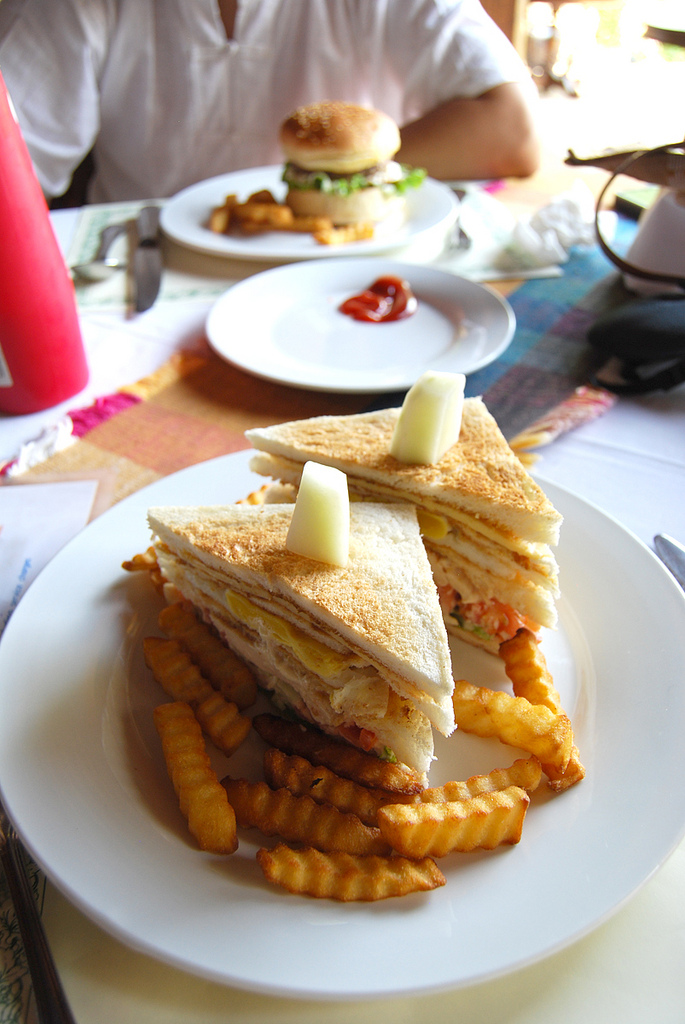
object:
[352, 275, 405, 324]
ketchup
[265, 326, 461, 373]
plate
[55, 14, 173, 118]
top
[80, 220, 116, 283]
spoon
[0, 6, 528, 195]
man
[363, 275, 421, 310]
glob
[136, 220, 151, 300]
knife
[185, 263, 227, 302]
place mat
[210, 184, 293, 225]
french fries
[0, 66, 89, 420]
bottle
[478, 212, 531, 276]
napkin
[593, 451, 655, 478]
table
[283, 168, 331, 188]
lettuce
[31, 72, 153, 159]
shirt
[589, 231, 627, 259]
strap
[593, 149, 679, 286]
bag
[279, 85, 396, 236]
bun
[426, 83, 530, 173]
elbow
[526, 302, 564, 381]
tablecloth